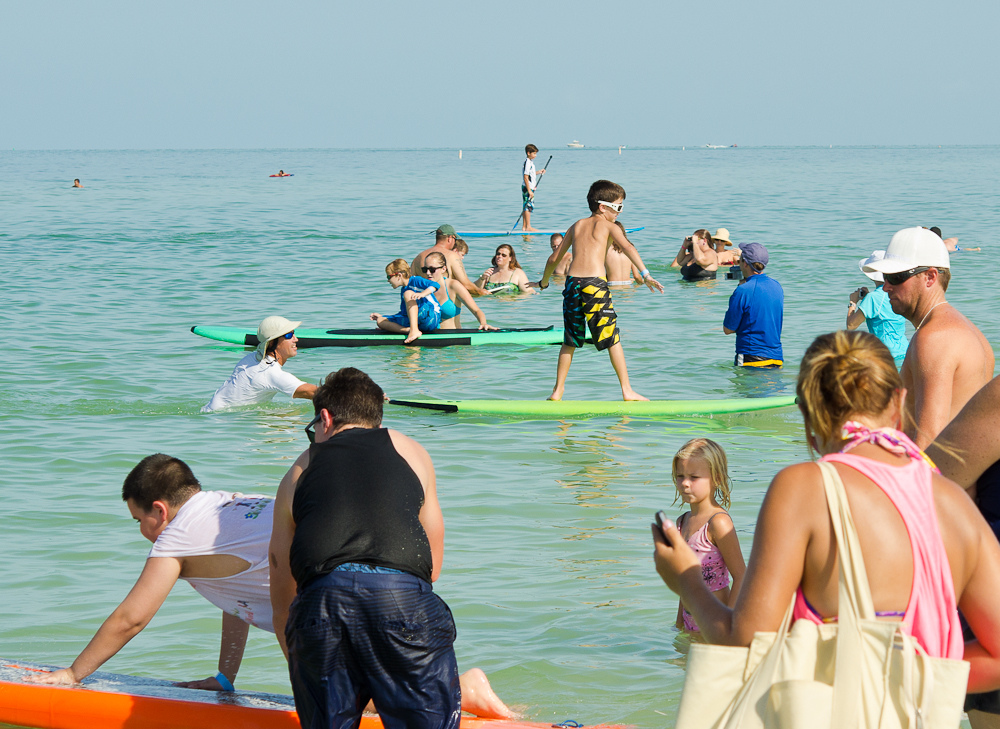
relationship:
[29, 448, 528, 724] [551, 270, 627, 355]
boy wearing surf shorts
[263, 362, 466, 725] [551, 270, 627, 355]
boy wearing surf shorts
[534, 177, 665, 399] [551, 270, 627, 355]
boy wearing surf shorts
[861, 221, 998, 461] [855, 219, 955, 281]
man wears hat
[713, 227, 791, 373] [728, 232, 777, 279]
man wears hat